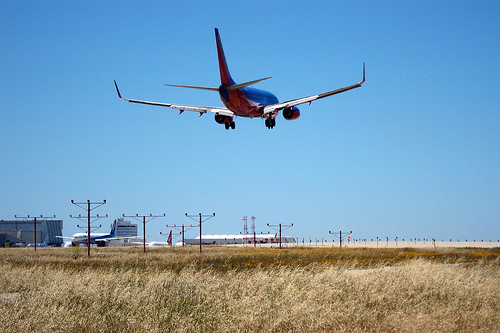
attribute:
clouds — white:
[406, 99, 475, 131]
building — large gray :
[2, 216, 65, 248]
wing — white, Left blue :
[100, 78, 208, 118]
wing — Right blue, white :
[258, 62, 365, 117]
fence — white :
[228, 237, 498, 254]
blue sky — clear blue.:
[374, 111, 491, 176]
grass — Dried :
[2, 242, 498, 330]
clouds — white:
[199, 232, 296, 238]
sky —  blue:
[34, 9, 85, 81]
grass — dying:
[2, 251, 472, 330]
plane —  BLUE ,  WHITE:
[107, 28, 369, 130]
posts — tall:
[34, 185, 441, 257]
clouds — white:
[120, 19, 190, 58]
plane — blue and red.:
[90, 21, 414, 143]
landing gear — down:
[197, 110, 282, 138]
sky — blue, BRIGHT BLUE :
[0, 0, 497, 242]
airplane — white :
[103, 22, 371, 134]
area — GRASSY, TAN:
[142, 270, 363, 300]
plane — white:
[76, 229, 164, 249]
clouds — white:
[411, 154, 467, 193]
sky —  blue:
[413, 32, 466, 140]